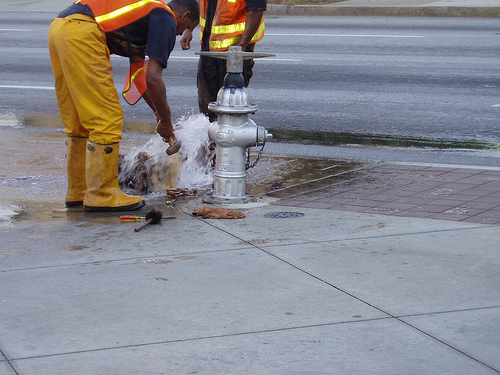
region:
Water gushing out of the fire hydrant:
[117, 113, 206, 192]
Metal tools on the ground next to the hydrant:
[113, 211, 179, 232]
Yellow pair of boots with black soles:
[58, 132, 148, 217]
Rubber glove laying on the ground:
[193, 198, 246, 223]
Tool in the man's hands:
[152, 113, 189, 163]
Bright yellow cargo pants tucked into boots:
[40, 12, 133, 147]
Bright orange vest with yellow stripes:
[195, 0, 270, 52]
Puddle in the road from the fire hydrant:
[12, 108, 497, 160]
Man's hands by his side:
[170, 27, 255, 55]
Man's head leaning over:
[166, 2, 200, 42]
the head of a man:
[150, 0, 205, 40]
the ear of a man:
[173, 8, 200, 33]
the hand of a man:
[154, 100, 194, 152]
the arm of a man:
[125, 2, 218, 180]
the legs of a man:
[37, 33, 133, 228]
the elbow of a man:
[136, 65, 171, 106]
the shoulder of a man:
[142, 0, 182, 52]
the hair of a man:
[159, 0, 225, 32]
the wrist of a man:
[147, 100, 181, 140]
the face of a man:
[173, 11, 195, 44]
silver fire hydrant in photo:
[181, 60, 287, 210]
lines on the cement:
[243, 214, 376, 366]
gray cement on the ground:
[159, 264, 245, 314]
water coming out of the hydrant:
[174, 113, 216, 169]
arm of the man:
[134, 43, 199, 149]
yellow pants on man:
[23, 14, 120, 166]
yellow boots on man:
[49, 124, 133, 229]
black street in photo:
[359, 41, 441, 106]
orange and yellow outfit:
[96, 0, 143, 38]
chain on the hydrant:
[241, 129, 276, 169]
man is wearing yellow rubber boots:
[34, 1, 207, 219]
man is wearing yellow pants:
[18, 0, 230, 226]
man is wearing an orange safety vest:
[45, 2, 205, 221]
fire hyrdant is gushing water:
[120, 64, 282, 224]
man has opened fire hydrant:
[45, 6, 283, 225]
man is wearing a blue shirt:
[36, 0, 282, 222]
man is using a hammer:
[43, 1, 269, 215]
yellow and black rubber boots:
[57, 134, 146, 220]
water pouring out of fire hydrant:
[125, 64, 277, 219]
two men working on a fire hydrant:
[39, 4, 274, 221]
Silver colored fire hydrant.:
[199, 83, 275, 206]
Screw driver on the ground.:
[118, 211, 178, 225]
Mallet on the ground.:
[132, 205, 165, 235]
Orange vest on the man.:
[62, 0, 195, 107]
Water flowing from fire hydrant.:
[119, 108, 220, 193]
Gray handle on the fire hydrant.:
[188, 44, 276, 76]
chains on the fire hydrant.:
[231, 139, 268, 167]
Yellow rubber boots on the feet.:
[57, 123, 149, 215]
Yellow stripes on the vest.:
[188, 11, 265, 54]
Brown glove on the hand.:
[189, 197, 246, 224]